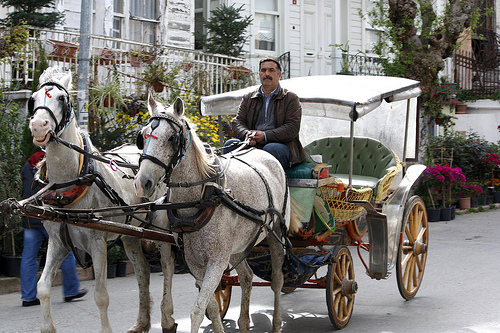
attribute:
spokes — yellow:
[353, 172, 442, 305]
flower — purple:
[423, 162, 473, 207]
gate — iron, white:
[15, 23, 308, 100]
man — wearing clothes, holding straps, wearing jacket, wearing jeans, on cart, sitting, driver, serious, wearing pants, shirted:
[215, 51, 338, 160]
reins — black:
[46, 98, 347, 213]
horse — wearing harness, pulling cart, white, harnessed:
[28, 77, 136, 262]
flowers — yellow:
[157, 86, 255, 154]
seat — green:
[283, 123, 397, 199]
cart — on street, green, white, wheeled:
[192, 49, 443, 252]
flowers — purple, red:
[412, 141, 480, 247]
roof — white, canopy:
[174, 60, 486, 154]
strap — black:
[43, 128, 268, 263]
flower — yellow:
[114, 72, 210, 147]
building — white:
[40, 14, 498, 74]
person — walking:
[2, 118, 105, 263]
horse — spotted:
[113, 98, 331, 263]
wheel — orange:
[378, 172, 465, 263]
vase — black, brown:
[400, 146, 475, 248]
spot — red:
[44, 88, 54, 107]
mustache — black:
[261, 75, 274, 82]